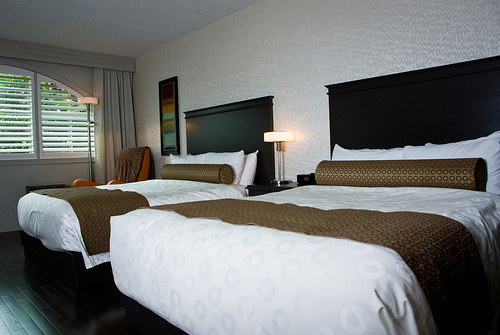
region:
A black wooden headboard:
[320, 48, 498, 184]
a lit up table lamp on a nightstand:
[260, 125, 295, 186]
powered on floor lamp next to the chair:
[72, 90, 103, 185]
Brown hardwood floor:
[6, 250, 131, 325]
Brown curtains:
[87, 56, 142, 176]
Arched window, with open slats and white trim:
[0, 56, 106, 161]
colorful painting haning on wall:
[150, 70, 190, 157]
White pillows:
[165, 147, 257, 177]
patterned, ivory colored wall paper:
[191, 35, 306, 87]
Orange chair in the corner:
[60, 145, 155, 197]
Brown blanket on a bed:
[143, 186, 413, 292]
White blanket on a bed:
[25, 168, 300, 258]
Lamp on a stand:
[252, 123, 305, 183]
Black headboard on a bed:
[167, 109, 277, 204]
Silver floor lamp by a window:
[59, 86, 130, 173]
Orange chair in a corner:
[111, 131, 173, 235]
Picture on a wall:
[137, 76, 215, 156]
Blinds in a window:
[5, 71, 112, 147]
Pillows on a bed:
[142, 141, 273, 195]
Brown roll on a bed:
[296, 153, 495, 213]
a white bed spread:
[129, 213, 289, 331]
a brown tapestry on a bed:
[222, 192, 422, 252]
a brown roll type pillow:
[313, 151, 480, 186]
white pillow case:
[331, 144, 402, 159]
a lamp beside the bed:
[252, 110, 304, 191]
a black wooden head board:
[324, 75, 496, 145]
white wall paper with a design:
[239, 18, 366, 73]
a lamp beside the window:
[67, 88, 106, 165]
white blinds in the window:
[4, 83, 30, 143]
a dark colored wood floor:
[7, 270, 54, 330]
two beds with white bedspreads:
[12, 47, 499, 329]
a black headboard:
[179, 84, 288, 183]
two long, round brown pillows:
[154, 159, 489, 189]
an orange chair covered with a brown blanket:
[68, 145, 153, 186]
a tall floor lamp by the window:
[75, 89, 103, 181]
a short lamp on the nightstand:
[258, 126, 295, 187]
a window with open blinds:
[3, 53, 101, 164]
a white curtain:
[90, 63, 142, 188]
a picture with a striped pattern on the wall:
[152, 73, 184, 155]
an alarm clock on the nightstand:
[292, 168, 316, 185]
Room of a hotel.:
[3, 5, 495, 330]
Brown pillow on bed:
[308, 153, 494, 193]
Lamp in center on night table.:
[256, 125, 298, 191]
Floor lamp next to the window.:
[72, 91, 106, 181]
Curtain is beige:
[89, 63, 141, 153]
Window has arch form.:
[0, 57, 99, 157]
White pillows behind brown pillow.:
[322, 132, 499, 159]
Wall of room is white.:
[161, 0, 495, 67]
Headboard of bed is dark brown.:
[316, 53, 497, 149]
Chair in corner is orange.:
[73, 144, 153, 191]